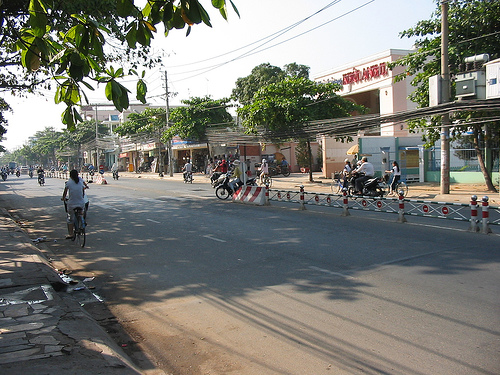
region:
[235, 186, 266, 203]
Red and white concret block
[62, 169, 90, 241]
Person in white riding bicycle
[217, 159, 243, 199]
Person in yellow shirt riding moped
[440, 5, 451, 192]
Tall brown electrical pole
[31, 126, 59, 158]
Tall green tree in distance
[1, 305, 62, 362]
Stone embedded into pavement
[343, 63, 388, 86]
Red sign on side of building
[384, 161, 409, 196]
Girl riding bicycle down street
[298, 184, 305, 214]
Short red and white caution pole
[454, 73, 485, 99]
Large square electrical box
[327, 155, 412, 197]
Group of people riding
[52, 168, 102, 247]
Girl with white shirt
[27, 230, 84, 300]
Garbage on the side of the road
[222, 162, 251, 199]
Man with yellow shirt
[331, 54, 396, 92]
Red letters on a tan building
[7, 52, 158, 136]
Green leaves on a tree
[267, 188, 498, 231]
Red and white saftey railing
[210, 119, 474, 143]
Electrical wires above people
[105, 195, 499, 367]
Gray road with shadows on ground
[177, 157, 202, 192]
Man with gray shirt riding motorcycle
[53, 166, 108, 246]
the woman is on the bicycle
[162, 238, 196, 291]
the shadow is on the road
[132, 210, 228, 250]
the lines are white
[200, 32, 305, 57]
the wires are thick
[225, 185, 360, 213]
the baracade s white and black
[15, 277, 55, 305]
the water is on the sidewalk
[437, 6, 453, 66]
the pole is wooden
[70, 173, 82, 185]
the hair is brown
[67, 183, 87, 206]
the shirt is white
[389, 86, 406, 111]
the wall is pink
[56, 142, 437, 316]
A street with lots of cyclist on it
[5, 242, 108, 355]
A sidewalk on the left side of the street.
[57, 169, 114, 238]
A girl in a white shirt on a bike on the left side of the road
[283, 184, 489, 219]
A fence median deviding the road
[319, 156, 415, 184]
A group of 4 bike riders together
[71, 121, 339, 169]
A strip of stores along the street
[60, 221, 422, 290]
Shadows cast from overhead trees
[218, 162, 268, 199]
A motor bike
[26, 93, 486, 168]
Trees planted along the sidewalk on the right side of the road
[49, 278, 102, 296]
Trash on the side of the road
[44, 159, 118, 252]
person riding bike on street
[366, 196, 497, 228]
white black and red guard rails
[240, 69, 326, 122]
tree covered in green leaves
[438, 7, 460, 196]
large brown electric pole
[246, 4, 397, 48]
electric lines running above street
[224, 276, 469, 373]
shadow of electric lines on road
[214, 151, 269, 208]
person on black motorbike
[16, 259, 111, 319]
water running off sidewalk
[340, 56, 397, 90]
red writing on side of building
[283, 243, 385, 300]
white line painted on road